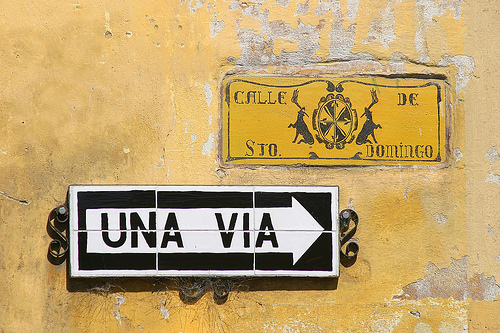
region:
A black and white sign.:
[128, 189, 262, 265]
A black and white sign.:
[102, 163, 221, 320]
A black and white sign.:
[153, 212, 210, 294]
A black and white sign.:
[188, 245, 239, 330]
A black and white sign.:
[178, 171, 247, 278]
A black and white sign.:
[183, 214, 276, 331]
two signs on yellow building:
[44, 29, 441, 327]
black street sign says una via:
[16, 164, 389, 308]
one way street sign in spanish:
[38, 173, 377, 302]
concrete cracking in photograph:
[209, 16, 456, 103]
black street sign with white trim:
[55, 149, 402, 284]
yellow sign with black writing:
[207, 44, 486, 204]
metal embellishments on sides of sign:
[3, 173, 423, 328]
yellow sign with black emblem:
[218, 61, 499, 191]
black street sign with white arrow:
[57, 183, 389, 288]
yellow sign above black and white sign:
[209, 63, 471, 269]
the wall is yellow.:
[3, 5, 494, 327]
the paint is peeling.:
[390, 245, 498, 307]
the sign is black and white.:
[41, 176, 364, 291]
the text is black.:
[92, 205, 290, 255]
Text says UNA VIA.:
[93, 203, 285, 264]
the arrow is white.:
[80, 189, 327, 264]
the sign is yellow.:
[212, 64, 457, 174]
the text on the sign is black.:
[226, 75, 440, 168]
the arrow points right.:
[80, 198, 328, 262]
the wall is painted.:
[2, 2, 495, 328]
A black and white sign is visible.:
[99, 189, 341, 287]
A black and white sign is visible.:
[69, 143, 262, 317]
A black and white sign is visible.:
[101, 173, 214, 283]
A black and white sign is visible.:
[113, 108, 248, 228]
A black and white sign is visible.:
[173, 221, 322, 328]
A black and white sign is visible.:
[172, 262, 232, 313]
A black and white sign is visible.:
[149, 253, 208, 293]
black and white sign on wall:
[69, 186, 349, 296]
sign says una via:
[66, 187, 354, 283]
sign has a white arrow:
[56, 188, 358, 300]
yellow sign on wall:
[202, 53, 497, 168]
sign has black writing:
[217, 72, 454, 180]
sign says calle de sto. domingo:
[215, 72, 474, 168]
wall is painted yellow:
[27, 14, 484, 326]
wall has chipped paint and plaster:
[40, 21, 469, 323]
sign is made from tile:
[58, 189, 349, 319]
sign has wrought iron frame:
[39, 181, 381, 318]